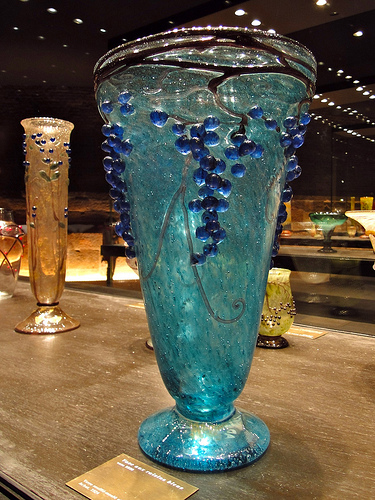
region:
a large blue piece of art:
[59, 37, 322, 487]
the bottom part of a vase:
[139, 391, 263, 475]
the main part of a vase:
[89, 77, 305, 409]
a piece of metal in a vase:
[136, 205, 208, 283]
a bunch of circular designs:
[165, 126, 250, 231]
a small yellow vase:
[241, 232, 294, 339]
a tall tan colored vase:
[20, 102, 95, 344]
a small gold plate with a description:
[77, 436, 177, 498]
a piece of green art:
[313, 202, 341, 257]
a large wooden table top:
[53, 371, 140, 450]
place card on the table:
[67, 450, 199, 498]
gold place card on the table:
[65, 451, 197, 499]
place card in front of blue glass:
[64, 450, 197, 499]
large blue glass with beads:
[90, 27, 318, 471]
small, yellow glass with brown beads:
[256, 268, 294, 349]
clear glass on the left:
[0, 208, 20, 300]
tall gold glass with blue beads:
[17, 118, 77, 334]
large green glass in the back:
[308, 210, 343, 254]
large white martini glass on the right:
[345, 210, 373, 271]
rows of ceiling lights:
[1, 1, 373, 150]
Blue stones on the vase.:
[168, 95, 262, 270]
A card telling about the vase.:
[78, 455, 199, 499]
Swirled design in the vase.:
[99, 40, 299, 101]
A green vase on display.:
[306, 202, 346, 256]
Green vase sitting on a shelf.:
[306, 201, 346, 260]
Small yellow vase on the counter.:
[251, 261, 296, 355]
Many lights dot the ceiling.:
[318, 19, 368, 152]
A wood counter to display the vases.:
[29, 336, 118, 445]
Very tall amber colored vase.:
[6, 98, 82, 349]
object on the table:
[254, 265, 297, 350]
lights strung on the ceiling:
[322, 56, 369, 155]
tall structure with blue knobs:
[17, 106, 86, 336]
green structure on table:
[308, 201, 347, 252]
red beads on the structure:
[1, 223, 27, 267]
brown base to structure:
[257, 335, 289, 354]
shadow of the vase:
[238, 406, 348, 499]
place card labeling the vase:
[57, 455, 225, 498]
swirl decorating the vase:
[203, 279, 251, 332]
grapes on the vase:
[74, 101, 322, 279]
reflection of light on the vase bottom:
[175, 422, 225, 464]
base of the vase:
[119, 397, 285, 473]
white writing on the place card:
[52, 442, 217, 497]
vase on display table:
[79, 18, 332, 486]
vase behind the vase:
[250, 263, 300, 363]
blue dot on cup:
[195, 255, 206, 267]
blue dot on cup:
[193, 223, 208, 243]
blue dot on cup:
[219, 178, 234, 200]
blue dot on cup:
[175, 134, 188, 157]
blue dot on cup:
[203, 113, 221, 129]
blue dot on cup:
[150, 109, 169, 128]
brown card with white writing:
[53, 441, 190, 499]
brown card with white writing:
[58, 448, 200, 497]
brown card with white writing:
[52, 449, 203, 494]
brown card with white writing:
[65, 449, 203, 494]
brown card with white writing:
[59, 446, 205, 494]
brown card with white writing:
[59, 450, 206, 497]